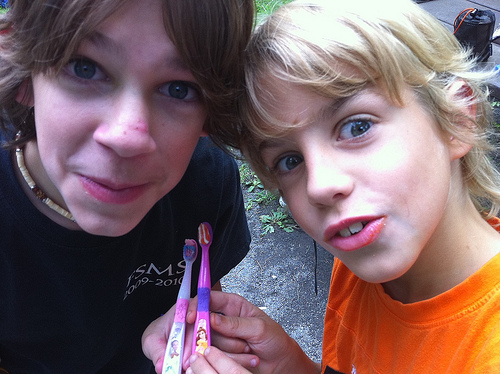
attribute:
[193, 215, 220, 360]
toothbrush — pink, purple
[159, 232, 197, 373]
toothbrush — pink, purple, disney frozen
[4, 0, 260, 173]
brown hair — dark brown, tan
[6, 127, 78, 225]
necklace — beaded, white, brown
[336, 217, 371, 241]
front teeth — white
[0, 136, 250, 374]
shirt — black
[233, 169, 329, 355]
pavement — grey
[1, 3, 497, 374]
boys — little, day time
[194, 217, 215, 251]
bristles — red, white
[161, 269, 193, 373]
handle — pink, blue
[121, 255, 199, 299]
letters — white